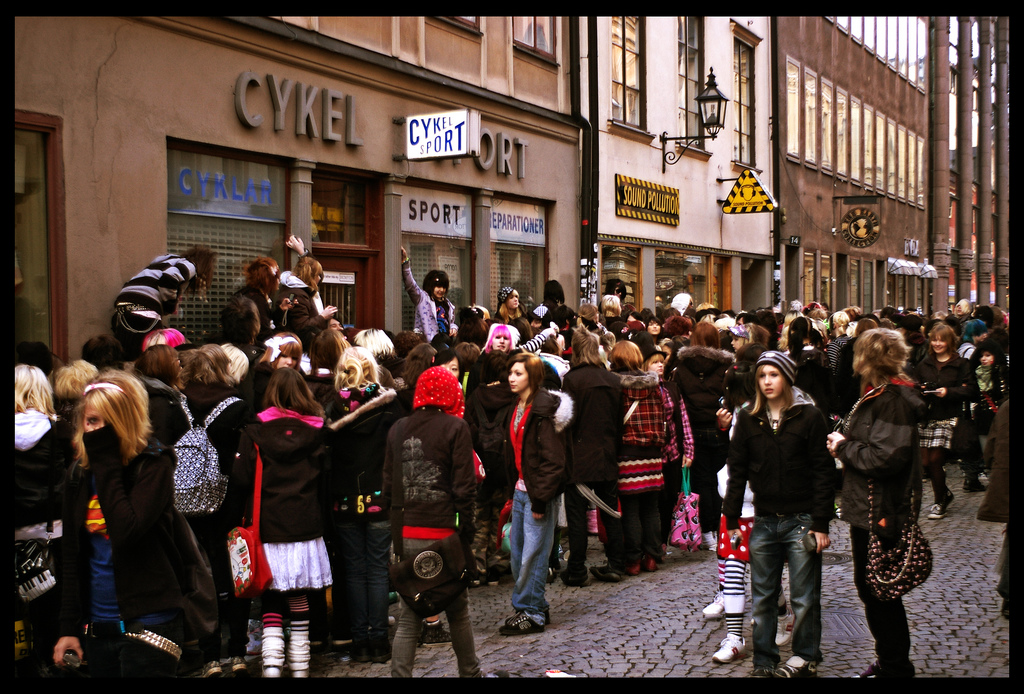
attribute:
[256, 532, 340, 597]
skirt — white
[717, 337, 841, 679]
person —  young 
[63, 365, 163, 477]
hair — straight , blonde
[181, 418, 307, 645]
bag — red